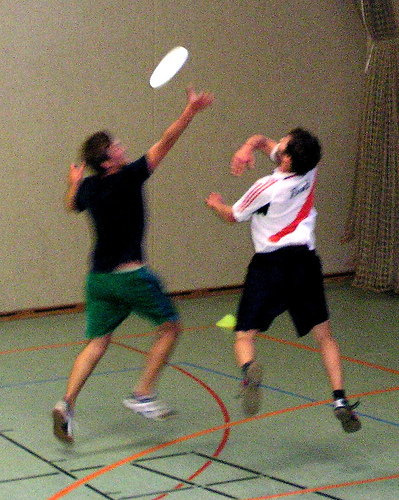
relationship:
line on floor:
[314, 488, 347, 498] [0, 284, 397, 498]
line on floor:
[120, 471, 267, 497] [0, 284, 397, 498]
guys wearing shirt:
[52, 85, 213, 444] [67, 152, 153, 273]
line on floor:
[209, 459, 272, 494] [0, 284, 397, 498]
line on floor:
[0, 430, 115, 497] [0, 284, 397, 498]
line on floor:
[191, 445, 343, 497] [0, 284, 397, 498]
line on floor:
[133, 461, 233, 497] [0, 284, 397, 498]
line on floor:
[127, 448, 195, 462] [0, 284, 397, 498]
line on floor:
[132, 448, 198, 462] [0, 284, 397, 498]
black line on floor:
[0, 445, 344, 499] [0, 284, 397, 498]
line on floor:
[117, 469, 259, 497] [0, 284, 397, 498]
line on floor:
[0, 444, 195, 482] [0, 284, 397, 498]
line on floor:
[0, 470, 59, 482] [0, 284, 397, 498]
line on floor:
[132, 449, 190, 462] [0, 284, 397, 498]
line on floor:
[68, 461, 104, 471] [0, 284, 397, 498]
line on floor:
[46, 457, 63, 469] [0, 284, 397, 498]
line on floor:
[112, 472, 259, 498] [0, 284, 397, 498]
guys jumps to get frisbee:
[205, 128, 364, 432] [147, 42, 186, 87]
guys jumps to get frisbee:
[52, 85, 213, 444] [147, 42, 186, 87]